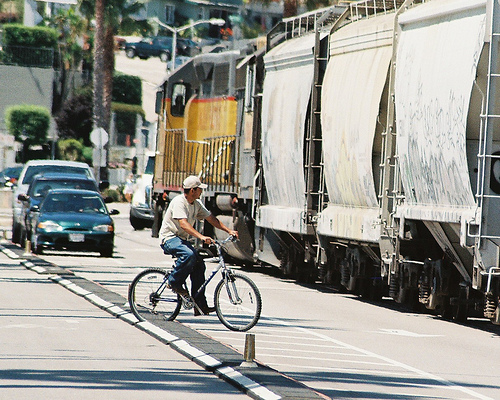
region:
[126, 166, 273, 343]
man riding on bicycle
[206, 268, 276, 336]
tire on the bicycle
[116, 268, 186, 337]
tire on the bicycle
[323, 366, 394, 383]
white mark on road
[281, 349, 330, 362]
white mark on road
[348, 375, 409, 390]
white mark on road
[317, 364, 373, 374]
white mark on road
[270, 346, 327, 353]
white mark on road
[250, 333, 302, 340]
white mark on road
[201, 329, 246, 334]
white mark on road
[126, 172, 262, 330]
A man sitting on a bicycle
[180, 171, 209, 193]
A white cap on the head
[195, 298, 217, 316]
The rider's foot on the ground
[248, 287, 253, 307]
Reflectors mounted on the spokes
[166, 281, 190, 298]
The rider's foot on the pedal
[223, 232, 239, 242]
A hand on the handle bar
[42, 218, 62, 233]
The sun's reflection on the front light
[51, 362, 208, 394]
A shadow cast on the street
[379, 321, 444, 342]
A white arrow painted on the street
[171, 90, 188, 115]
Driver of the freight train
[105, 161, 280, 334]
Man riding a bicycle down the street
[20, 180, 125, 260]
Emerald green car driving down the street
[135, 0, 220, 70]
White lamp post with two lights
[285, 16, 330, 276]
Metal ladder on the side of the vehicle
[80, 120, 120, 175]
Back of a sign post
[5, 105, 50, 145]
Square cut bush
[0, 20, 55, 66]
Square cut bush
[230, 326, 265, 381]
Post in the middle of the road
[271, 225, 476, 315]
Black wheels on the road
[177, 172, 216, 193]
White baseball cap on man's head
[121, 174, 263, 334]
man riding a bicycle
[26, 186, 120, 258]
dard green parked car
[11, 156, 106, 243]
white parked truck behind cars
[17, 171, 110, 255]
car parked in between other cars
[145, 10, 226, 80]
top of white lampost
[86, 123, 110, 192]
back of sign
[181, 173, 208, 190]
white hat worn by man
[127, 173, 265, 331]
man wearing blue jeans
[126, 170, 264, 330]
man wearing a t-shirt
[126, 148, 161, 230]
half of front of truck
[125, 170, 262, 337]
Man riding a bicycle on the street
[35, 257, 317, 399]
Straight concrete partition on the street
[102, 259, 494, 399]
White colored road markings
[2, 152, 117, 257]
Three cars in a row on the street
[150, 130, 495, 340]
Train on a track beside a street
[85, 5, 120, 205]
Two tall tree stems side by side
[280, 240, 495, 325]
Wheels of a train wagon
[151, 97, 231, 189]
Yellow paint on a train engine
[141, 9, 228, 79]
Top of a lamp post with two lighting ends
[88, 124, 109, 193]
Sign post on the street